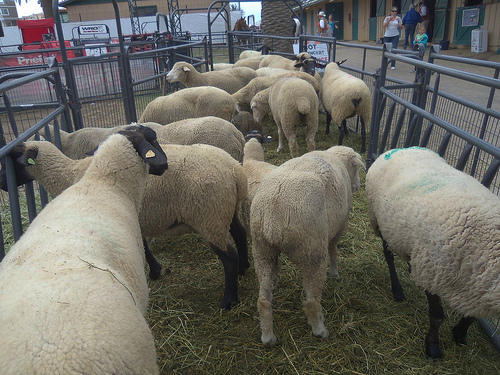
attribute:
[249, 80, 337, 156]
sheep — white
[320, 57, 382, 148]
sheep — standing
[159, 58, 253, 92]
sheep — standing, cream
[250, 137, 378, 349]
sheep — standing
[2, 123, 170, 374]
sheep — white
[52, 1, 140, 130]
pen — metal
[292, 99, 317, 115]
tail — stubby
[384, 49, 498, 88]
rail — metal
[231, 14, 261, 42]
horse — brown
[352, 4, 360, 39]
stall — green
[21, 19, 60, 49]
booth — red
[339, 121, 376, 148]
legs — black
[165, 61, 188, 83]
face — white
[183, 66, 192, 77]
ear — white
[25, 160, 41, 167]
tag — green, yellow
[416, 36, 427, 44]
shirt — multicolor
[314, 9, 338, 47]
person — wearing hat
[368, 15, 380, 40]
door — green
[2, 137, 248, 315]
sheep — black, face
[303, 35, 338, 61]
fence — gray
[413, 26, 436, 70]
child — standing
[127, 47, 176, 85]
bar — metal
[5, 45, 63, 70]
sign — red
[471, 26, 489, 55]
stand — white